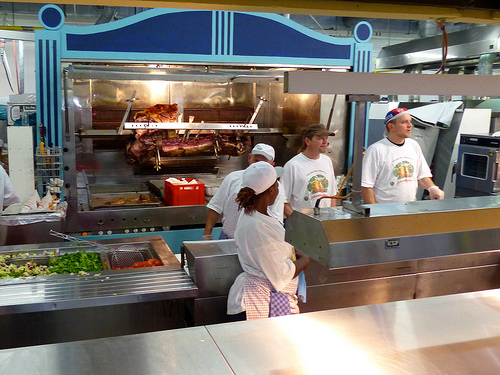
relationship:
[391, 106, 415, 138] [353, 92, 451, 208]
head of man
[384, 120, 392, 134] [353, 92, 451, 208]
ear of man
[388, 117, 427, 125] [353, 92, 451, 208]
eyes of man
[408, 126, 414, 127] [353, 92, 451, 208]
nose of man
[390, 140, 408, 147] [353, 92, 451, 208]
neck of man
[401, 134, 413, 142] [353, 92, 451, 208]
chin of man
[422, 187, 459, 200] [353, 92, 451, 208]
hand of man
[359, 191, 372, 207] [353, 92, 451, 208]
arm of man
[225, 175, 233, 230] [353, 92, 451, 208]
body of man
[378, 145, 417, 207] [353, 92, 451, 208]
shirt of man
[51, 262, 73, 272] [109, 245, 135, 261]
lettuce in pan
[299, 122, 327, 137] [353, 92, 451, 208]
cap on man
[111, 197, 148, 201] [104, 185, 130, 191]
meat on grill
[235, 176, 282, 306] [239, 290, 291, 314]
woman wearing apron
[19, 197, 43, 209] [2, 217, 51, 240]
garbage in bin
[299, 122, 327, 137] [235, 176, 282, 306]
cap on woman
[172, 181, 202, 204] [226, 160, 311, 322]
crate behind woman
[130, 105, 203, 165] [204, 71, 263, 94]
food in compartment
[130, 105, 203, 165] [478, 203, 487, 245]
food in counter top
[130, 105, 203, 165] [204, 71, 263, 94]
food on compartment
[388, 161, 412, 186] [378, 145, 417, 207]
design on shirt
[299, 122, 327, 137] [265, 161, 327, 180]
cap on shir